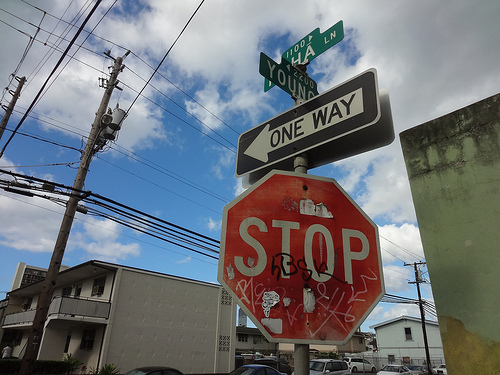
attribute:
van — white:
[303, 350, 360, 374]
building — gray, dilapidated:
[23, 246, 243, 373]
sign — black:
[234, 67, 394, 182]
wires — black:
[78, 190, 220, 260]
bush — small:
[91, 360, 121, 374]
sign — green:
[264, 20, 344, 91]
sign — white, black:
[157, 154, 428, 353]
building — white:
[2, 263, 217, 373]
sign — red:
[198, 168, 399, 350]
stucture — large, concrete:
[376, 106, 499, 371]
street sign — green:
[258, 53, 316, 101]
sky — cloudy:
[2, 2, 499, 262]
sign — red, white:
[216, 167, 386, 346]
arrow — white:
[238, 86, 364, 162]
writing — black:
[266, 93, 353, 148]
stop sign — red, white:
[218, 165, 387, 345]